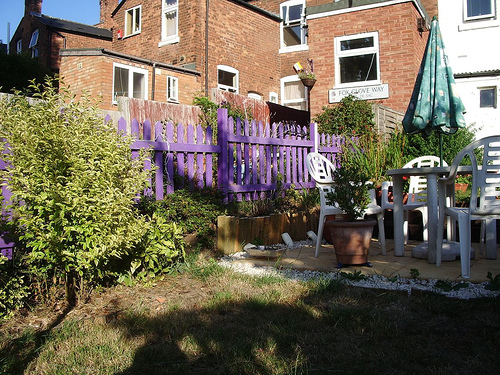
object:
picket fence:
[0, 108, 361, 260]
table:
[384, 165, 482, 265]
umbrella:
[398, 15, 465, 168]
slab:
[228, 236, 500, 283]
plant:
[323, 163, 371, 221]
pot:
[326, 219, 378, 267]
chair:
[304, 151, 388, 259]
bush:
[0, 72, 160, 301]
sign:
[328, 82, 388, 104]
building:
[435, 0, 499, 169]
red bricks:
[0, 0, 437, 122]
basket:
[298, 78, 316, 88]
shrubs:
[151, 187, 221, 233]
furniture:
[434, 134, 499, 279]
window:
[333, 30, 381, 88]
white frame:
[276, 0, 311, 55]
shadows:
[1, 238, 500, 374]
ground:
[0, 252, 499, 374]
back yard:
[0, 0, 499, 374]